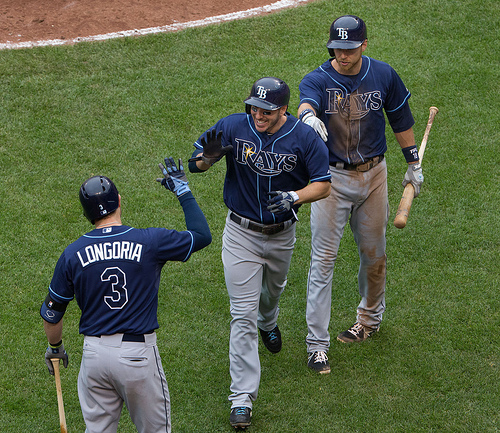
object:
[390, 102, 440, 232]
bat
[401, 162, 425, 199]
hand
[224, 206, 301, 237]
belt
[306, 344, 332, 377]
shoes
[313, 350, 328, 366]
laces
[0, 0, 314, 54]
border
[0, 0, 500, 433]
field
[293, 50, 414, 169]
jersey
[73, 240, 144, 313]
longoria 3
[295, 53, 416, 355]
uniform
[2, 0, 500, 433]
grass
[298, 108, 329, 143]
glove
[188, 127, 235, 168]
glove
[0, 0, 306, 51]
clay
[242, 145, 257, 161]
star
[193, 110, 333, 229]
shirt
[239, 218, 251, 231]
holder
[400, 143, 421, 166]
wrist band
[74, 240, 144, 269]
name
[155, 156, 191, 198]
gloves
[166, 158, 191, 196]
two tones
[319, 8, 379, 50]
helmet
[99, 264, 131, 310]
number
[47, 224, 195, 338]
jersey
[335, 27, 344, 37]
t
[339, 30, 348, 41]
b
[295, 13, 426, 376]
player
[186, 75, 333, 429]
player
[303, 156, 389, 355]
pants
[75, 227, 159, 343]
back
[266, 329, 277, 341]
laces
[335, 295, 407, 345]
cleat